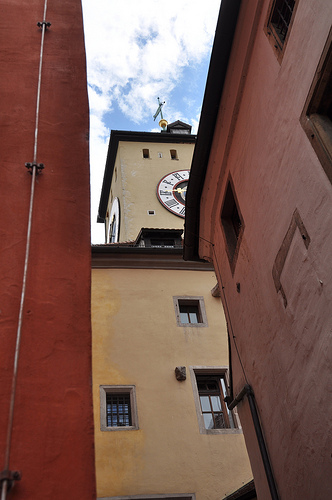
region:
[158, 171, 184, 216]
A clock on the tower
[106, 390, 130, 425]
A window on the building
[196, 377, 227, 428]
The window is rectangular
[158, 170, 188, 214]
Roman numerals on the clock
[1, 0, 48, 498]
A pole on the side of the building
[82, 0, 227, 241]
The sky above the buildings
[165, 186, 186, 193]
A hand on the clock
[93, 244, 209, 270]
The ledge of the roof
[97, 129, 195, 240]
A clocktower on the roof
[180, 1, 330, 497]
A building below the clocktower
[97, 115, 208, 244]
A clock tower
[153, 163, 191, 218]
A large clock on a building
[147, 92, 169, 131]
A wind dial on a buidling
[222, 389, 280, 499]
Pipe on the side of a building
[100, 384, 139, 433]
A closed window of a building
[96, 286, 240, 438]
Windows on a building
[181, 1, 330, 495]
A tall red building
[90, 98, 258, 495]
A tan building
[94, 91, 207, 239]
Clock tower section of building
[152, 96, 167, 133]
A weathervane adorning a roof.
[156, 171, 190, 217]
A large clock face on the side of a brown building.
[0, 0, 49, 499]
Metal pipes running up the wall of a tall, red building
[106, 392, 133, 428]
Metal bars fortifying a window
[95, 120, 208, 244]
A steeple tower mounted atop a beige, 3-story building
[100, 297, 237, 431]
Windows on a building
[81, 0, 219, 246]
Clouds float through a blue sky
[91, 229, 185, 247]
Brown roof tiles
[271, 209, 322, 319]
An old window which has been plastered over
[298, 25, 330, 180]
A wooden door frame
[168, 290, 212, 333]
A window on a building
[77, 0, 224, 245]
White clouds in the sky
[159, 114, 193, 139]
Chimney on top of building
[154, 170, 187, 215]
Clock on a tower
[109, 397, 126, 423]
Bars on a window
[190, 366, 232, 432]
Window on a building